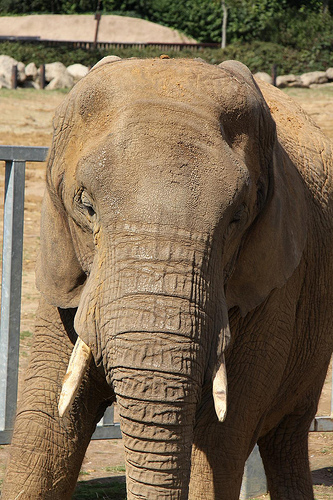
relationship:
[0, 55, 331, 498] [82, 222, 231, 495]
elephant has trunk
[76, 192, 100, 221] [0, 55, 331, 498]
eye on elephant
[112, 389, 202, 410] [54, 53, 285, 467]
wrinkle on elephant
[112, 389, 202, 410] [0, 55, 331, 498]
wrinkle on elephant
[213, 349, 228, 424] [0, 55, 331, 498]
tusk on elephant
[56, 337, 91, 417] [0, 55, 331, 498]
tusk on elephant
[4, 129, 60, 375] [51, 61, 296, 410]
gate behind elephant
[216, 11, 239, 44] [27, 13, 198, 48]
trees behind building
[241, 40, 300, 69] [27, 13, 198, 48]
bushes behind building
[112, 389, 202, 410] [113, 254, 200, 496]
wrinkle on front of trunk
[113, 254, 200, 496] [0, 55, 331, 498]
trunk on elephant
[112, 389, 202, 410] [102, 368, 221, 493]
wrinkle on elephant trunk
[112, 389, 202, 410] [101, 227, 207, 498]
wrinkle on trunk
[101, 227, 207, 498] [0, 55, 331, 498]
trunk on elephant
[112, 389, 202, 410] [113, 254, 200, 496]
wrinkle on trunk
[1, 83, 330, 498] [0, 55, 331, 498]
dirt on elephant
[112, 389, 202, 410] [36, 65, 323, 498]
wrinkle on elephant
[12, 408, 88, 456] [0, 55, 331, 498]
wrinkle on elephant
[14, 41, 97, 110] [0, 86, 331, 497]
boulders on edge of enclosure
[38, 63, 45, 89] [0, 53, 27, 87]
posts mounted by boulders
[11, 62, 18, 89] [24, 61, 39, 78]
posts mounted by boulders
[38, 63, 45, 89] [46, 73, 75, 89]
posts mounted by boulders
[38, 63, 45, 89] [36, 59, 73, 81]
posts mounted by boulders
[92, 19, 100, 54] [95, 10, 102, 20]
pole with transformer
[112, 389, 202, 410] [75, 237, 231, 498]
wrinkle on trunk